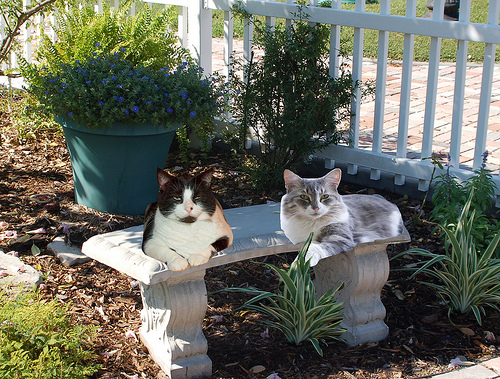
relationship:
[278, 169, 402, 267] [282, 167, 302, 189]
cat has ear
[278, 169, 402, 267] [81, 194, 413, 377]
cat laying on bench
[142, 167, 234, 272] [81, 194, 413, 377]
cat laying on bench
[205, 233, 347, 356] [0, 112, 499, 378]
plant growing from soil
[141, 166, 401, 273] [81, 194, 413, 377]
cats laying on bench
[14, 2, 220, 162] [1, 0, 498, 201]
plant next to fence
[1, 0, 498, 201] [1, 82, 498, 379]
fence inside of garden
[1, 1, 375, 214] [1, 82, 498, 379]
plants inside garden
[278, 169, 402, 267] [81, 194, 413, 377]
cat sitting on bench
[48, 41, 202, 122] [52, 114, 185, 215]
flowers inside pot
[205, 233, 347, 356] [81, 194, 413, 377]
plant under bench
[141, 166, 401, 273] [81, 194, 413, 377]
cats sitting on bench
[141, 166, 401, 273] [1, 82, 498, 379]
cats sitting in garden